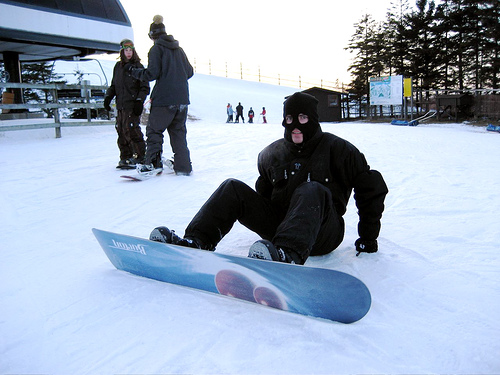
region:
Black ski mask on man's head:
[275, 90, 317, 142]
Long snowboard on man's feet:
[87, 230, 369, 327]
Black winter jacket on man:
[258, 135, 387, 234]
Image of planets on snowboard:
[212, 263, 292, 310]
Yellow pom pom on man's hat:
[150, 10, 162, 24]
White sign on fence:
[367, 73, 404, 105]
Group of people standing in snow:
[224, 99, 267, 122]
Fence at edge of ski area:
[187, 54, 356, 91]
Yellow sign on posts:
[400, 73, 418, 119]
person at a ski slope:
[138, 85, 393, 272]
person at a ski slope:
[106, 31, 151, 168]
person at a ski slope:
[139, 8, 194, 175]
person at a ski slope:
[256, 99, 269, 124]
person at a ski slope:
[243, 106, 256, 124]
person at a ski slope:
[233, 99, 248, 122]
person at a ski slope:
[220, 98, 237, 120]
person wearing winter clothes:
[140, 81, 396, 276]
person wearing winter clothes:
[143, 10, 195, 182]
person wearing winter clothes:
[99, 38, 151, 169]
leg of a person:
[199, 175, 270, 229]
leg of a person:
[283, 195, 339, 244]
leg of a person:
[118, 115, 145, 155]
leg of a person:
[140, 120, 175, 160]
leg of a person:
[171, 122, 207, 159]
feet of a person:
[240, 220, 290, 262]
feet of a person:
[129, 160, 173, 182]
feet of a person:
[116, 155, 141, 167]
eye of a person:
[294, 110, 310, 124]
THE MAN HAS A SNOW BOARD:
[87, 216, 382, 332]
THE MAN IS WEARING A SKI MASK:
[275, 87, 328, 158]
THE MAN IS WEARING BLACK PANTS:
[175, 170, 346, 270]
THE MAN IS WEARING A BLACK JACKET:
[245, 135, 390, 240]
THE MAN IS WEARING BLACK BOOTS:
[146, 224, 296, 269]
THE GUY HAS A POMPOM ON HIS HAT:
[153, 11, 164, 23]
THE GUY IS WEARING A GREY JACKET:
[142, 28, 198, 109]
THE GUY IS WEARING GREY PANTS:
[136, 100, 202, 176]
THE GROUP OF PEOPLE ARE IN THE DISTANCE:
[215, 95, 275, 126]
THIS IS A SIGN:
[363, 68, 408, 111]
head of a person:
[279, 85, 326, 158]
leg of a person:
[188, 181, 242, 245]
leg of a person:
[266, 194, 333, 248]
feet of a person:
[139, 230, 226, 270]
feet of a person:
[225, 235, 302, 272]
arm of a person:
[345, 154, 416, 234]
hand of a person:
[348, 239, 403, 261]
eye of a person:
[294, 113, 313, 123]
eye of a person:
[276, 107, 296, 124]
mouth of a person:
[286, 125, 308, 136]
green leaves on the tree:
[464, 23, 479, 58]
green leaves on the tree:
[440, 36, 472, 71]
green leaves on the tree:
[395, 32, 430, 66]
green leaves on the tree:
[365, 12, 416, 57]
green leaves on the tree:
[414, 20, 445, 64]